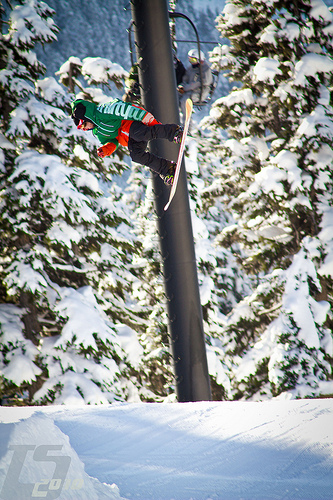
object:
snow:
[0, 398, 333, 499]